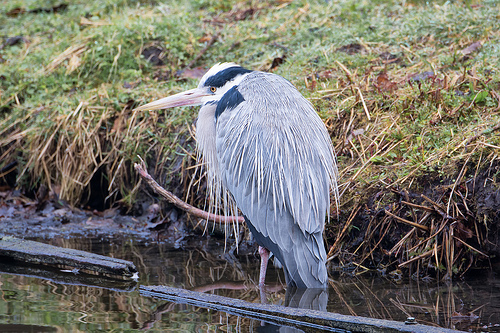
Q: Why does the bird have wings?
A: To be able to fly.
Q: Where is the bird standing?
A: In the water.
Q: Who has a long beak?
A: The bird.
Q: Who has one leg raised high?
A: A bird.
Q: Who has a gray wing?
A: Bird.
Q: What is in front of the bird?
A: A stick.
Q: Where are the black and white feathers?
A: On the bird's head.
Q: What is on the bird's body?
A: Long grey feathers.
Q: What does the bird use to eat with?
A: The long tan beak.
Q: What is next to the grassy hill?
A: A water area.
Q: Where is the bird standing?
A: In the water.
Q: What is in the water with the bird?
A: Sticks and debris.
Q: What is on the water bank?
A: Green grass.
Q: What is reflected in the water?
A: The grass and stick.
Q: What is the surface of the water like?
A: It is calm.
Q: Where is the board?
A: In the water.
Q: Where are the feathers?
A: On the bird.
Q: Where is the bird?
A: In the water.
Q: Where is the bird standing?
A: In the water.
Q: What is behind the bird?
A: Grass.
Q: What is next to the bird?
A: A board.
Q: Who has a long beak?
A: The bird.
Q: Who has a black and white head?
A: The bird.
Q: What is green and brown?
A: The grass.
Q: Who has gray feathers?
A: The bird.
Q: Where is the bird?
A: In water.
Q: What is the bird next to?
A: Near grass.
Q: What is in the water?
A: Wood.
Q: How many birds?
A: 1.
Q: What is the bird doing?
A: Standing.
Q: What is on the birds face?
A: Beak.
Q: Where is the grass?
A: Behind the bird.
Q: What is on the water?
A: Bird.